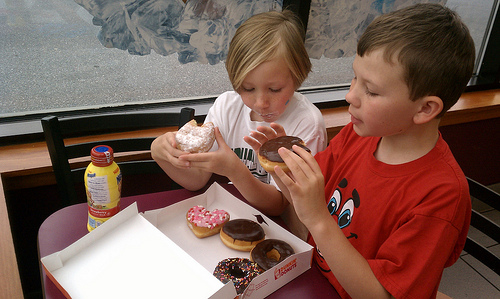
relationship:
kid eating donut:
[218, 17, 312, 216] [179, 122, 215, 150]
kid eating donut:
[332, 16, 480, 298] [258, 137, 306, 169]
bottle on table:
[88, 146, 116, 226] [38, 209, 332, 296]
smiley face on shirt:
[320, 181, 362, 264] [317, 136, 466, 289]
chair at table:
[48, 117, 194, 188] [38, 209, 332, 296]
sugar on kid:
[258, 110, 278, 120] [218, 17, 312, 216]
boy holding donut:
[332, 16, 480, 298] [258, 137, 306, 169]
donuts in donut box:
[184, 204, 232, 239] [35, 183, 309, 298]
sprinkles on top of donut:
[224, 255, 255, 266] [217, 257, 262, 290]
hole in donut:
[265, 249, 283, 260] [253, 241, 291, 271]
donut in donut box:
[225, 217, 261, 248] [35, 183, 309, 298]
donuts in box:
[224, 222, 294, 267] [38, 209, 332, 296]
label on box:
[269, 263, 306, 275] [35, 183, 309, 298]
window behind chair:
[0, 2, 494, 104] [48, 117, 194, 188]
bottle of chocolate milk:
[83, 142, 121, 230] [88, 146, 116, 226]